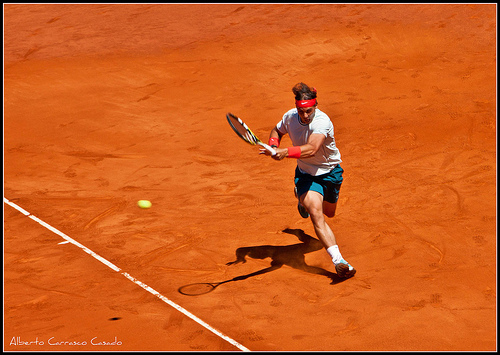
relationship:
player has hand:
[258, 82, 357, 276] [271, 144, 315, 161]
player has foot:
[258, 82, 357, 276] [333, 258, 355, 277]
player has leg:
[258, 82, 357, 276] [311, 211, 355, 276]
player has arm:
[258, 82, 357, 276] [271, 120, 329, 160]